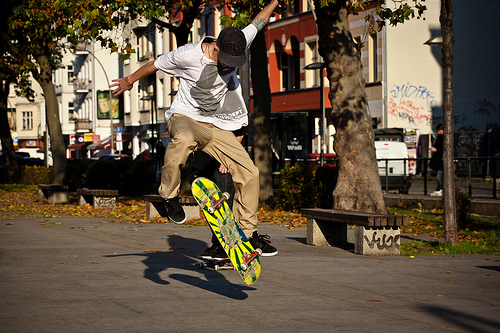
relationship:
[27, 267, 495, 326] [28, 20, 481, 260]
ground in photo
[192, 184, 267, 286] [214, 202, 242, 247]
skateboard has base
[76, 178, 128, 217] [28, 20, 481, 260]
bench in photo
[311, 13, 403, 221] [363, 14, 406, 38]
tree has stem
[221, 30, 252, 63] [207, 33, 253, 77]
cap on head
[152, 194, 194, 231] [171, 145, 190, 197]
shoe on leg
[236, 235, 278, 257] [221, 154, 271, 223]
shoe on leg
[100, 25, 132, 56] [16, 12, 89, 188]
stem on tree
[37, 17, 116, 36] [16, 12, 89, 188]
branches on tree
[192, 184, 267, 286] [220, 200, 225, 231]
skateboard has lines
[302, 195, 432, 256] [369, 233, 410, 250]
bench has graffiti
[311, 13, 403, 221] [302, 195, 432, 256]
tree behind bench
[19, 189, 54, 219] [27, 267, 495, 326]
leaves on ground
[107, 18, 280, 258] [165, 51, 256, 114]
boy wearing shirt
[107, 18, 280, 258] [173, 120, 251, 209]
boy wearing pants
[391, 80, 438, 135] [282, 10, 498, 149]
graffiti on building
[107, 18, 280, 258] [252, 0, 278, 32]
boy has arm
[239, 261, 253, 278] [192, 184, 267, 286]
wheel on skateboard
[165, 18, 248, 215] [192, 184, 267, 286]
boy riding skateboard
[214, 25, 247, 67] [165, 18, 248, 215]
cap on boy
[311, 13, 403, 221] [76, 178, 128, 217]
tree by bench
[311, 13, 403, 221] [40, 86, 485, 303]
tree in park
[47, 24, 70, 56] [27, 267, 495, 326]
leaves on ground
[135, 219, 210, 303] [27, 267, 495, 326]
shadow on ground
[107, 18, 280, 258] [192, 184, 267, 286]
boy on skateboard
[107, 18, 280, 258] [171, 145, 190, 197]
boy has leg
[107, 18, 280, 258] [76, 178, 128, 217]
boy near bench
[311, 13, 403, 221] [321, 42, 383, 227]
tree has trunk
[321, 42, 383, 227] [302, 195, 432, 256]
trunk next to bench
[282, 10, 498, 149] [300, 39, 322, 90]
building has window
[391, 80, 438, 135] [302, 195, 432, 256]
graffiti on bench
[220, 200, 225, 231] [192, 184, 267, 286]
lines on skateboard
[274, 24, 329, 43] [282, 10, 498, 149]
ledge on building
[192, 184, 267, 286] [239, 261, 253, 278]
skateboard has wheel